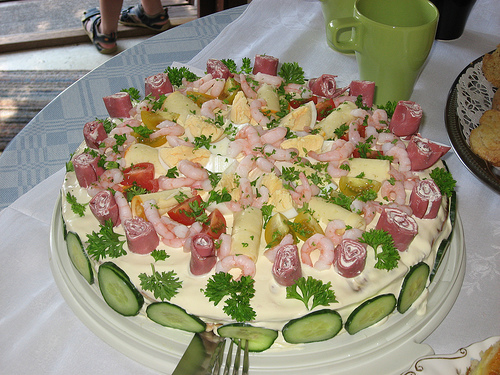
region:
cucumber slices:
[341, 268, 421, 324]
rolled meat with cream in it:
[267, 241, 301, 278]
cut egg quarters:
[276, 100, 322, 132]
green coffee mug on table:
[324, 1, 439, 106]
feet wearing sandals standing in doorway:
[67, 4, 181, 45]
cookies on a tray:
[467, 45, 498, 159]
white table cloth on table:
[222, 4, 327, 64]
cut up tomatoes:
[169, 184, 206, 221]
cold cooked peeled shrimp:
[217, 251, 257, 276]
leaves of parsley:
[194, 271, 274, 317]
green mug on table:
[320, 5, 436, 85]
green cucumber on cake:
[286, 312, 343, 347]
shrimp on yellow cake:
[303, 233, 334, 270]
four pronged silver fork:
[213, 336, 248, 373]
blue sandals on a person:
[71, 3, 171, 50]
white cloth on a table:
[13, 206, 55, 339]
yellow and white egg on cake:
[234, 97, 249, 128]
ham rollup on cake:
[330, 242, 365, 269]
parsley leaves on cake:
[204, 272, 262, 324]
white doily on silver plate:
[456, 67, 484, 132]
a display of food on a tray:
[55, 51, 448, 354]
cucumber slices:
[60, 245, 145, 316]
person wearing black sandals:
[63, 0, 184, 55]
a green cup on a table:
[325, 1, 445, 102]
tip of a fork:
[212, 335, 262, 371]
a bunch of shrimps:
[226, 121, 296, 169]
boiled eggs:
[275, 93, 325, 155]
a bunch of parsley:
[203, 270, 260, 321]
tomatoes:
[118, 161, 158, 189]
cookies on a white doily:
[459, 45, 499, 184]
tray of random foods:
[63, 51, 460, 348]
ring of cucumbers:
[59, 206, 454, 341]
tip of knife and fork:
[165, 328, 252, 373]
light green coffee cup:
[328, 7, 450, 105]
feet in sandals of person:
[80, 2, 192, 58]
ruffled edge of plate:
[390, 338, 496, 374]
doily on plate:
[458, 64, 498, 134]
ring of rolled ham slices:
[63, 51, 453, 288]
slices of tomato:
[118, 157, 234, 243]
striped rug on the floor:
[0, 68, 88, 142]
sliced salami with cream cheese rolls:
[331, 231, 364, 281]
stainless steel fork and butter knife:
[177, 336, 249, 373]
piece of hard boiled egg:
[268, 90, 320, 136]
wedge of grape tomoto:
[118, 160, 161, 191]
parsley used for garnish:
[85, 220, 125, 260]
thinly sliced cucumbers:
[87, 251, 409, 356]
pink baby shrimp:
[225, 120, 292, 177]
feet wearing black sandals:
[57, 1, 174, 59]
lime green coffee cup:
[323, 0, 441, 111]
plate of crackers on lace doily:
[444, 37, 499, 187]